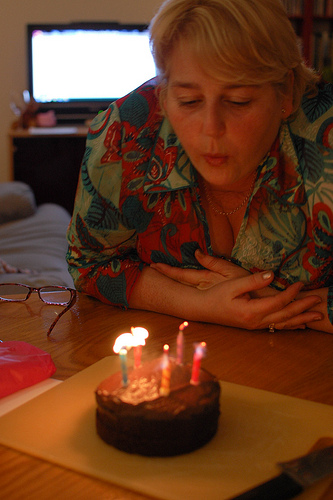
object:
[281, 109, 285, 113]
earring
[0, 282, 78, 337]
glasses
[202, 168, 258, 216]
necklace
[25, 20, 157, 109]
t.v.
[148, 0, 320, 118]
blondehair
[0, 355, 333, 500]
paper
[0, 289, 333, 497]
table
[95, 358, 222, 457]
cake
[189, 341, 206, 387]
candle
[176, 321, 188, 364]
candle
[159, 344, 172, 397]
candle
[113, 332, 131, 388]
candle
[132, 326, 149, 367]
candle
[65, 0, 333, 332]
woman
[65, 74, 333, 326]
shirt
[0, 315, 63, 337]
table